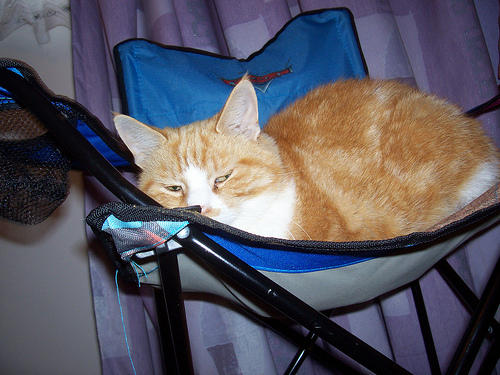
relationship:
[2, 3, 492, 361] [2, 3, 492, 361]
dayton city took place in dayton city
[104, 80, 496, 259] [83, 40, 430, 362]
cat lying on chair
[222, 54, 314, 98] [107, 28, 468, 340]
logo on chair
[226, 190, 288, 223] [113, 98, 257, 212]
whisker on cat's face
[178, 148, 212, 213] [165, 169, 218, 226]
spot on cat's nose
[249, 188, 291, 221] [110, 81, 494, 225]
spot on cat's neck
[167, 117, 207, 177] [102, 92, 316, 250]
stripes on top of cat's head